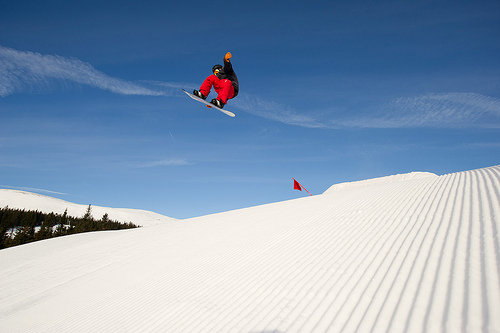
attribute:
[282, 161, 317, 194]
flag — red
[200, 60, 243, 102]
suit — red and black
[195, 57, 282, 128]
suit — red and black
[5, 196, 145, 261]
trees — background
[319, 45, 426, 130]
sky — clear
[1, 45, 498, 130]
cloud — sparse, white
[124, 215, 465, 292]
snow — covering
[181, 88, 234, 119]
snowboard — white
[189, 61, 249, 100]
snowsuit — red and black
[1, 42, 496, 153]
clouds — white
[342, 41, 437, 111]
sky — clear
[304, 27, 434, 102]
sky — blue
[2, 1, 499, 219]
sky — clear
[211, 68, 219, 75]
goggles — yellow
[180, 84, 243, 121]
snowboard — white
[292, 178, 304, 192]
flag — red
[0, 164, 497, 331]
slope — white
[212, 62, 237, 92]
jacket — black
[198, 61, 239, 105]
snow suit — red and black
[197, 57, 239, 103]
snow suit — red and black